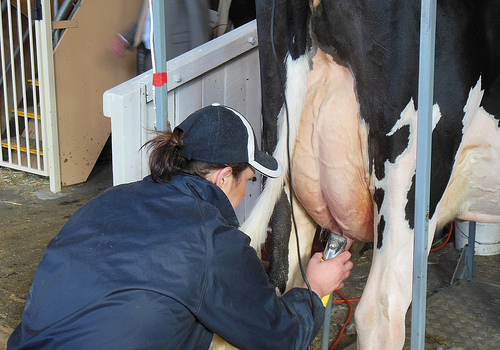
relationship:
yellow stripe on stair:
[2, 136, 45, 159] [6, 86, 58, 175]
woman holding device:
[5, 100, 356, 349] [314, 228, 351, 307]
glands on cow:
[290, 103, 369, 221] [233, 1, 498, 348]